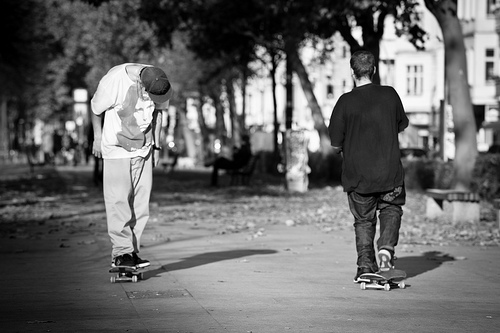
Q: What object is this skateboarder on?
A: Skateboard.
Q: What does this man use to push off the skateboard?
A: Leg.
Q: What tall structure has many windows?
A: Building.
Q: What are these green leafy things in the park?
A: Trees.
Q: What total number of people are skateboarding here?
A: Two.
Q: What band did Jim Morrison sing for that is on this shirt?
A: Doors.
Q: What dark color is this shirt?
A: Black.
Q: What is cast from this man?
A: Shadow.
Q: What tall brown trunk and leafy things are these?
A: Trees.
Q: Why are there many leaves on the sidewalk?
A: It's fall.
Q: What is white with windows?
A: Buildings.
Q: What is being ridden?
A: Skateboard.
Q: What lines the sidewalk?
A: Trees.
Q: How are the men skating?
A: On boards.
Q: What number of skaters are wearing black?
A: One.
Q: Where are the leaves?
A: Ground.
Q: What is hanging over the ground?
A: Trees.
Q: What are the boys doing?
A: Skateboarding.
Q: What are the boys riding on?
A: Skateboards.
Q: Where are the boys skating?
A: Park.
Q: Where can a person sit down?
A: Bench.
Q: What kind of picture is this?
A: Black and white.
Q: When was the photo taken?
A: Daytime.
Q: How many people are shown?
A: Two.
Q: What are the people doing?
A: Skateboarding.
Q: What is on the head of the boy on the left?
A: Cap.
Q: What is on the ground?
A: Leaves.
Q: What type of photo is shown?
A: Black and white.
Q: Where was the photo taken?
A: City sidewalk.